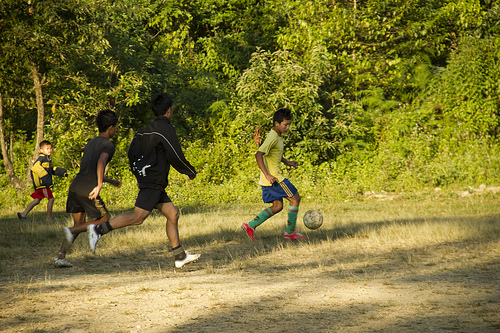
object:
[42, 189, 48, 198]
strips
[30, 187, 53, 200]
red shorts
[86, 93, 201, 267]
boy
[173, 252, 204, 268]
shoes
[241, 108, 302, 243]
boy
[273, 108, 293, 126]
black hair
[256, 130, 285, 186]
t-shirt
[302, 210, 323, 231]
ball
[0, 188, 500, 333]
ground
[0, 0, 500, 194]
shrub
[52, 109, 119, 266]
boy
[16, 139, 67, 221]
boy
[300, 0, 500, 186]
leaves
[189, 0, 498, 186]
trees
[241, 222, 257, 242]
shoe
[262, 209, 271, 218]
stripe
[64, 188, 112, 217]
shorts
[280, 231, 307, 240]
shoes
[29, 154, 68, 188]
jacket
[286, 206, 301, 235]
knee sock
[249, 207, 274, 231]
knee sock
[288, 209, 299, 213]
stripe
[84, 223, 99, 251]
tennis shoe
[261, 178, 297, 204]
shorts